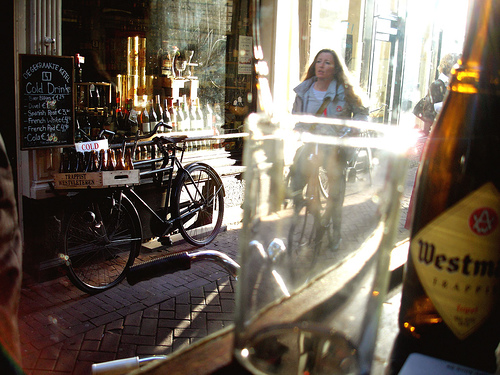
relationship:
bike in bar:
[55, 122, 227, 293] [0, 1, 499, 373]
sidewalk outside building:
[20, 167, 416, 374] [1, 0, 496, 272]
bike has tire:
[55, 122, 227, 293] [57, 190, 147, 294]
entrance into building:
[361, 1, 402, 124] [1, 0, 496, 272]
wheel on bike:
[178, 167, 227, 246] [55, 122, 227, 293]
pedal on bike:
[158, 235, 171, 247] [55, 122, 227, 293]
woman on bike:
[294, 49, 369, 121] [283, 150, 344, 282]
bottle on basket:
[58, 148, 135, 175] [54, 168, 142, 190]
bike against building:
[55, 122, 227, 293] [1, 0, 496, 272]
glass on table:
[232, 111, 414, 373] [131, 238, 497, 371]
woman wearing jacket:
[294, 49, 369, 121] [288, 76, 351, 118]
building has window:
[1, 0, 496, 272] [62, 0, 259, 135]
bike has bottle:
[55, 122, 227, 293] [58, 148, 135, 175]